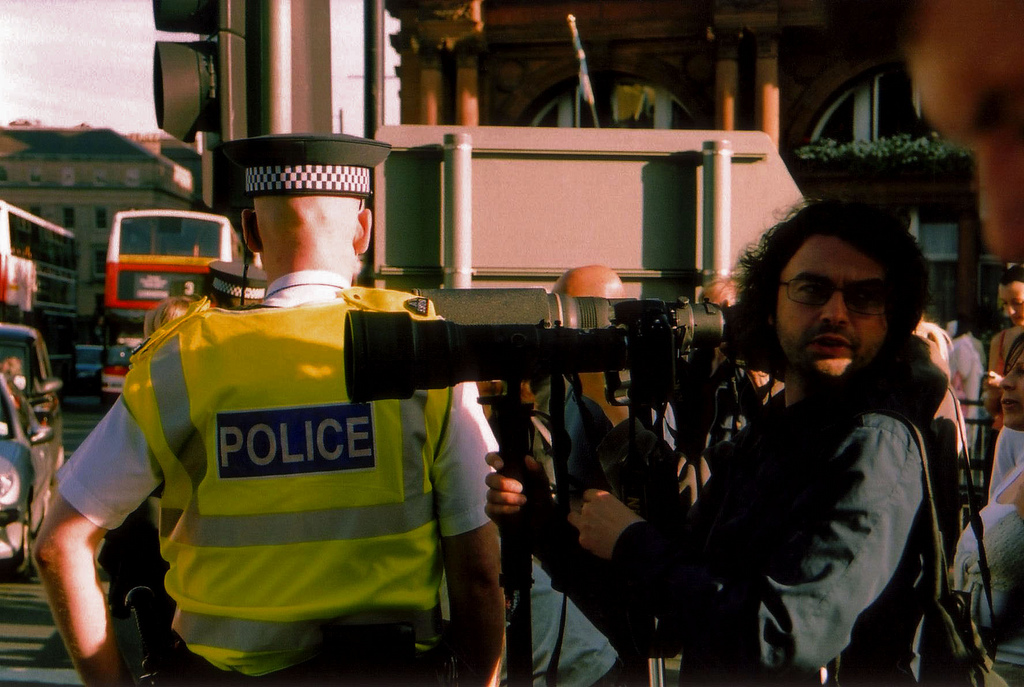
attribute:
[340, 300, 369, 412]
lens — large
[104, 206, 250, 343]
city bus — yellow, red, yellow and red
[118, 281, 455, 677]
vest — yellow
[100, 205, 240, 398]
bus — double decker, red 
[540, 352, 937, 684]
jacket — hooded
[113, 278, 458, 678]
police vest — yellow and  black, yellow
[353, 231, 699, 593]
camera — black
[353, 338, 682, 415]
lense — camera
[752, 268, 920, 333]
glasses — black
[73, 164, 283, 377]
bus — black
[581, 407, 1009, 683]
top — black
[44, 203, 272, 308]
bus — white